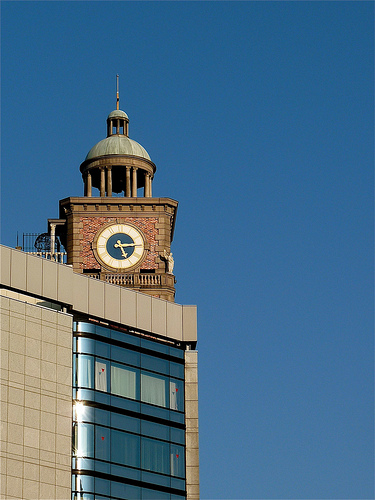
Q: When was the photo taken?
A: 5:15.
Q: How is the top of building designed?
A: Domed columns.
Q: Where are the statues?
A: Balcony.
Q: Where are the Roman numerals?
A: On the clock face.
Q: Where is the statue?
A: On the ledge of the clock tower.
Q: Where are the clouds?
A: There are none.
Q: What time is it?
A: 5:15.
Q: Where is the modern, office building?
A: In front of the clock tower.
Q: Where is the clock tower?
A: Behind the modern, office building.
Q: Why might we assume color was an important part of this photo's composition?
A: Because the photographer framed the photo with a predominance of blue.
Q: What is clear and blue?
A: Sky.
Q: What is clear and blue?
A: The sky.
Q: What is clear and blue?
A: The sky.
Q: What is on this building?
A: Blue glass window.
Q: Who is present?
A: No one.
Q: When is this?
A: Daytime.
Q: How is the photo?
A: Visible.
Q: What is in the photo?
A: Clock.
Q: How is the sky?
A: Clear.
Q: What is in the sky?
A: Nothing.